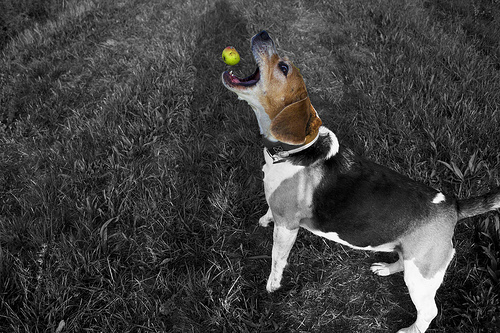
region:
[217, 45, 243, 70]
Small piece of greenish read fruit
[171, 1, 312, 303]
Shadow of human taking the picture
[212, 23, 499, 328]
Tri-colored black white and brown beagle dog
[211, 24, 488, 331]
TRi-colored beagle catching a piece of fruit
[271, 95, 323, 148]
large brown floppy beagle ear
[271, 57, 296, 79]
black beagle eye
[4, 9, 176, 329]
Grass in black and white coloration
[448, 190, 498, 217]
Beagle dog tail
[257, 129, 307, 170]
dark dog collar and tag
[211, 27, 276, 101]
beagle dog mouth and teeth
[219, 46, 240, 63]
The apple is green and red.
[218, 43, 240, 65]
The apple is round.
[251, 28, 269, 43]
The dogs nose is black.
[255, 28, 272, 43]
The dogs nose is small.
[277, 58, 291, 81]
The dogs eye is black.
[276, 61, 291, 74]
The dogs eye is small.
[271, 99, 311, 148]
The dogs ear is brown.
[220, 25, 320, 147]
The dogs face is black, white and brown.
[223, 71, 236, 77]
The dog teeth are white.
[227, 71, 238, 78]
The dogs teeth are sharp.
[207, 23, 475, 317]
Dog catching a yellow ball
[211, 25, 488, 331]
Dog catching a ball with mouth open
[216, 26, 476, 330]
Four legged dog catching ball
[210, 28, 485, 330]
Four legged dog looking at camera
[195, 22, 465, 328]
Four legged dog have white spot on tail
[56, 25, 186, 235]
High level green grass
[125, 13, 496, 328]
Dog on grass catching yellow ball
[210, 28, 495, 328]
Four legged dog on grass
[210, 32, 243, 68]
Yellow ball to be caught by dog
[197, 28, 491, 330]
Four legged dog is brown and white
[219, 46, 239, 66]
A small apple in the air.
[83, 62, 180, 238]
The grass is tall.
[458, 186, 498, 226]
The dog's tail is short.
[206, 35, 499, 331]
This is a dog trying to catch an apple.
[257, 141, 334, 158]
The dog is wearing a white collar.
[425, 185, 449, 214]
A white patch among the black fur of the dog.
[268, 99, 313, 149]
The dog's floppy ear.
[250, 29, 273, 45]
The black nose of the dog.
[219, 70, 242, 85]
The dog has only a few teeth.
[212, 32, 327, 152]
The head of the dog, in profile.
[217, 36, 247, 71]
green apple above dog's mouth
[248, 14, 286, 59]
black nose on dog's mouth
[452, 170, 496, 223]
dog's tail on right side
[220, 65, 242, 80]
white teeth in dog's mouth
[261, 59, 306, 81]
dogs eye on side of face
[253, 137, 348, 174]
collar on dog's neck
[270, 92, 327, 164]
brown ear on side of dog's head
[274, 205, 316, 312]
white front leg on left side of dog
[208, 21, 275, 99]
dog's open mouth facing left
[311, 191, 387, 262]
dark patch of fur on dog's belly